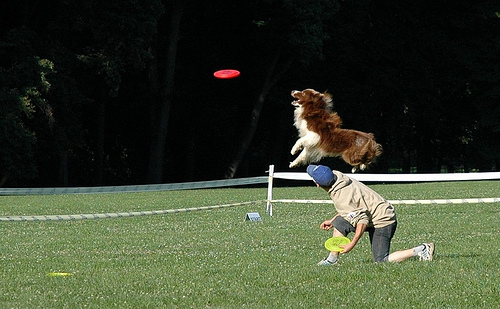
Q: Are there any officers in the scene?
A: No, there are no officers.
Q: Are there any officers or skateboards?
A: No, there are no officers or skateboards.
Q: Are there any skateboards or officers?
A: No, there are no officers or skateboards.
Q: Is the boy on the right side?
A: Yes, the boy is on the right of the image.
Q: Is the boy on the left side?
A: No, the boy is on the right of the image.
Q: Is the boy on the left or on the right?
A: The boy is on the right of the image.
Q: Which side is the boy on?
A: The boy is on the right of the image.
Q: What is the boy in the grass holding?
A: The boy is holding the frisbee.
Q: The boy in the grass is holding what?
A: The boy is holding the frisbee.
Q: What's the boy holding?
A: The boy is holding the frisbee.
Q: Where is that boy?
A: The boy is in the grass.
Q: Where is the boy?
A: The boy is in the grass.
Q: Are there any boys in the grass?
A: Yes, there is a boy in the grass.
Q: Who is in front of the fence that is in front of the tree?
A: The boy is in front of the fence.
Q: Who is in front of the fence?
A: The boy is in front of the fence.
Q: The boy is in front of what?
A: The boy is in front of the fence.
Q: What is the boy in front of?
A: The boy is in front of the fence.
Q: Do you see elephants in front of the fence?
A: No, there is a boy in front of the fence.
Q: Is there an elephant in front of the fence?
A: No, there is a boy in front of the fence.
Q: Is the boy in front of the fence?
A: Yes, the boy is in front of the fence.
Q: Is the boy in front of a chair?
A: No, the boy is in front of the fence.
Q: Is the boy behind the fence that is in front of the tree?
A: No, the boy is in front of the fence.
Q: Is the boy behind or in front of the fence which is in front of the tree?
A: The boy is in front of the fence.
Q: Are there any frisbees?
A: Yes, there is a frisbee.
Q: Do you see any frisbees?
A: Yes, there is a frisbee.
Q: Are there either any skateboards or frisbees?
A: Yes, there is a frisbee.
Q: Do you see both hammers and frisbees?
A: No, there is a frisbee but no hammers.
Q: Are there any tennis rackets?
A: No, there are no tennis rackets.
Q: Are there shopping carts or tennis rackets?
A: No, there are no tennis rackets or shopping carts.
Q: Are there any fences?
A: Yes, there is a fence.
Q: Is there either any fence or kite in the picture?
A: Yes, there is a fence.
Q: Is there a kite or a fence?
A: Yes, there is a fence.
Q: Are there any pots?
A: No, there are no pots.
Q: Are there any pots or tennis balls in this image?
A: No, there are no pots or tennis balls.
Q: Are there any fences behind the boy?
A: Yes, there is a fence behind the boy.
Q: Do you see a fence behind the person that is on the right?
A: Yes, there is a fence behind the boy.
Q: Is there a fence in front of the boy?
A: No, the fence is behind the boy.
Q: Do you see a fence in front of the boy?
A: No, the fence is behind the boy.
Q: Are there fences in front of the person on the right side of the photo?
A: No, the fence is behind the boy.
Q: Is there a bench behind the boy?
A: No, there is a fence behind the boy.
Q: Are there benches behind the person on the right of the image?
A: No, there is a fence behind the boy.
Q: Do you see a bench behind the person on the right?
A: No, there is a fence behind the boy.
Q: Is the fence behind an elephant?
A: No, the fence is behind a boy.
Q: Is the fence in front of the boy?
A: No, the fence is behind the boy.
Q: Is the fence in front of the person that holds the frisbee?
A: No, the fence is behind the boy.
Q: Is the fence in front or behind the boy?
A: The fence is behind the boy.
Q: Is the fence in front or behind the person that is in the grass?
A: The fence is behind the boy.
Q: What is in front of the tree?
A: The fence is in front of the tree.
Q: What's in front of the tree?
A: The fence is in front of the tree.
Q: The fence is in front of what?
A: The fence is in front of the tree.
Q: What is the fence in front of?
A: The fence is in front of the tree.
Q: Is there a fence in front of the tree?
A: Yes, there is a fence in front of the tree.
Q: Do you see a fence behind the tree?
A: No, the fence is in front of the tree.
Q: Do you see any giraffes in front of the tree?
A: No, there is a fence in front of the tree.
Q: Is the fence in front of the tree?
A: Yes, the fence is in front of the tree.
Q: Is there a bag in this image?
A: No, there are no bags.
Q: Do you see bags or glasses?
A: No, there are no bags or glasses.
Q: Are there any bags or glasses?
A: No, there are no bags or glasses.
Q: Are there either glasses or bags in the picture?
A: No, there are no bags or glasses.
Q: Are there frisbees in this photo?
A: Yes, there is a frisbee.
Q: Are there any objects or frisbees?
A: Yes, there is a frisbee.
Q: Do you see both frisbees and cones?
A: No, there is a frisbee but no cones.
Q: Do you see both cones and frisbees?
A: No, there is a frisbee but no cones.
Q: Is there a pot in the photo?
A: No, there are no pots.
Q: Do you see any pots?
A: No, there are no pots.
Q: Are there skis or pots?
A: No, there are no pots or skis.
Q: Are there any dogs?
A: Yes, there is a dog.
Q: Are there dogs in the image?
A: Yes, there is a dog.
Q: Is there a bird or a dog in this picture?
A: Yes, there is a dog.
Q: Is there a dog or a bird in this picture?
A: Yes, there is a dog.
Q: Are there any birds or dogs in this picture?
A: Yes, there is a dog.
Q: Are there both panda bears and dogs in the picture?
A: No, there is a dog but no panda bears.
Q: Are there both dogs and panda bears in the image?
A: No, there is a dog but no panda bears.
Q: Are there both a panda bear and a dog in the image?
A: No, there is a dog but no panda bears.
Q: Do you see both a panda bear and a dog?
A: No, there is a dog but no panda bears.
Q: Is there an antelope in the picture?
A: No, there are no antelopes.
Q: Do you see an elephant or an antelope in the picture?
A: No, there are no antelopes or elephants.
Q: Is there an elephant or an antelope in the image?
A: No, there are no antelopes or elephants.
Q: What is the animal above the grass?
A: The animal is a dog.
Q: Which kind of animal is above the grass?
A: The animal is a dog.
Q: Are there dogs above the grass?
A: Yes, there is a dog above the grass.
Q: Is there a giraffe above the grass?
A: No, there is a dog above the grass.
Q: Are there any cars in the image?
A: No, there are no cars.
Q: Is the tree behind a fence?
A: Yes, the tree is behind a fence.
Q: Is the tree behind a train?
A: No, the tree is behind a fence.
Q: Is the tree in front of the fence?
A: No, the tree is behind the fence.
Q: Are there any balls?
A: No, there are no balls.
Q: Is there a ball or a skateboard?
A: No, there are no balls or skateboards.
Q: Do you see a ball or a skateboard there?
A: No, there are no balls or skateboards.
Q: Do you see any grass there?
A: Yes, there is grass.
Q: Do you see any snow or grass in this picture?
A: Yes, there is grass.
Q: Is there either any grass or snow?
A: Yes, there is grass.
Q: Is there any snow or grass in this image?
A: Yes, there is grass.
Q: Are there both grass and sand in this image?
A: No, there is grass but no sand.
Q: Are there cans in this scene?
A: No, there are no cans.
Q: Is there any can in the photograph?
A: No, there are no cans.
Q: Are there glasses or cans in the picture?
A: No, there are no cans or glasses.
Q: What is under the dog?
A: The grass is under the dog.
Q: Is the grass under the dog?
A: Yes, the grass is under the dog.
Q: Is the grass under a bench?
A: No, the grass is under the dog.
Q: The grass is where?
A: The grass is on the ground.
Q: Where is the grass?
A: The grass is on the ground.